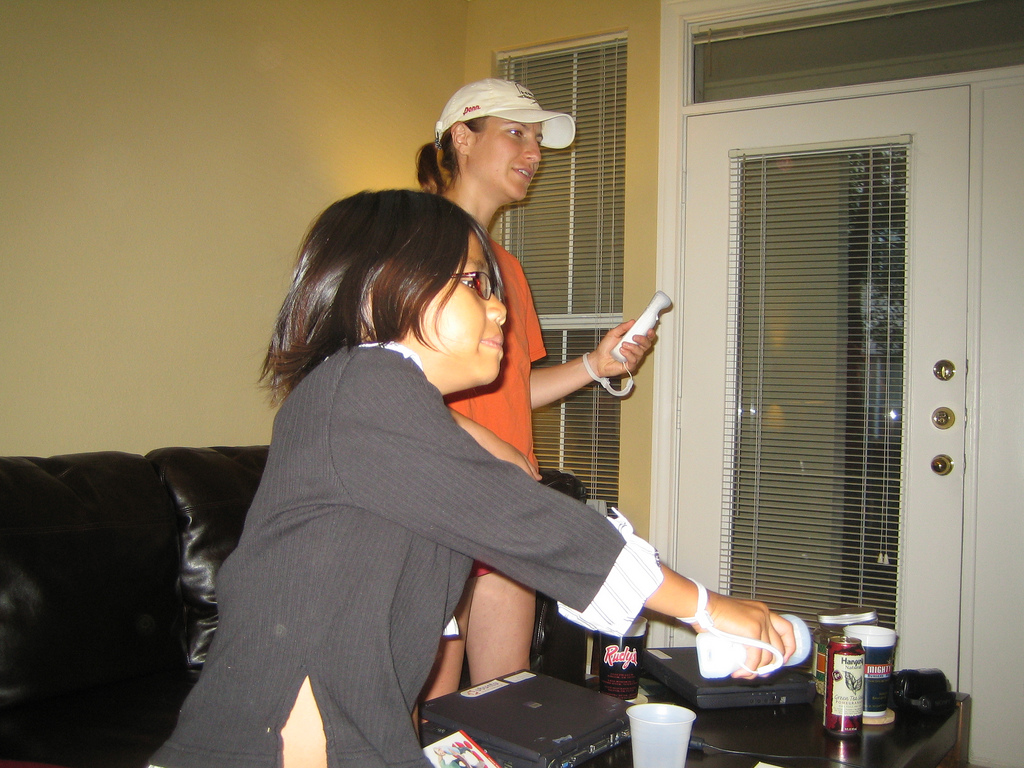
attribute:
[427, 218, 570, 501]
shirt — orange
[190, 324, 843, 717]
shirt — grey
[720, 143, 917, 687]
blinds — mini, slanted, open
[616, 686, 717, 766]
cup — opaque, plastic, drinking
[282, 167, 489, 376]
hair — cut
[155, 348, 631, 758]
jacket — long, sleeved, gray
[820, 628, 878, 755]
can — purple, soft drink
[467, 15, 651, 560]
blinds — open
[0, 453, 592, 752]
couch — black, leather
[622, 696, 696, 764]
cup — empty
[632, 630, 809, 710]
laptop — black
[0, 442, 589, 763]
sofa — black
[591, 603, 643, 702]
cup — white, black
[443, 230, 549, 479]
shirt — orange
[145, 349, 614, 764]
sweater — gray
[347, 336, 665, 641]
shirt — white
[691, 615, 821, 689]
wii controller — units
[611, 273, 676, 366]
wii controller — units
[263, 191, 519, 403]
hair — brown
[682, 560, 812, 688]
strap — white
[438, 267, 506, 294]
glasses — brown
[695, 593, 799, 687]
hand — girls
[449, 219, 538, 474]
shirt — orange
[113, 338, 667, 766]
shirt — gray, pinstripe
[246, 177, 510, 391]
hair — brown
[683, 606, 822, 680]
wii remote — white